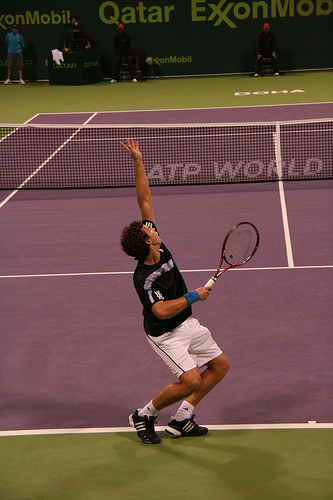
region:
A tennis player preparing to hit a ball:
[118, 135, 263, 447]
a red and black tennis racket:
[203, 222, 262, 288]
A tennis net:
[0, 115, 330, 190]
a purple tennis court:
[0, 101, 332, 435]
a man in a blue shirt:
[4, 25, 26, 83]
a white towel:
[50, 48, 63, 64]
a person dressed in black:
[253, 20, 281, 76]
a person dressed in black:
[110, 23, 142, 84]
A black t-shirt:
[132, 217, 193, 336]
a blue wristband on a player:
[182, 287, 201, 305]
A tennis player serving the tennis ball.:
[111, 137, 251, 446]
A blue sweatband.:
[182, 287, 199, 305]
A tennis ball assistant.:
[2, 23, 28, 88]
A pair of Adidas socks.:
[137, 399, 200, 422]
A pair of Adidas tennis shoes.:
[128, 407, 210, 446]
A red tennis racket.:
[199, 218, 264, 296]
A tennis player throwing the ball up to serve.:
[96, 134, 261, 446]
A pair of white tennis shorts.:
[137, 314, 238, 380]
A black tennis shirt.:
[119, 211, 203, 335]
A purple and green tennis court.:
[1, 87, 331, 445]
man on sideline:
[4, 21, 26, 88]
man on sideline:
[111, 19, 135, 86]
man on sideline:
[252, 20, 281, 78]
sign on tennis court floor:
[232, 86, 308, 95]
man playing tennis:
[62, 124, 263, 439]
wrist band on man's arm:
[181, 286, 200, 300]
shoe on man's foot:
[130, 409, 159, 443]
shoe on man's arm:
[161, 413, 205, 435]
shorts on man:
[144, 316, 221, 367]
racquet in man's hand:
[201, 206, 268, 301]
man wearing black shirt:
[89, 137, 271, 445]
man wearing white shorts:
[124, 212, 246, 446]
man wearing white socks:
[123, 211, 228, 463]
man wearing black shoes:
[118, 202, 240, 454]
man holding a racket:
[85, 103, 327, 459]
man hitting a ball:
[122, 116, 242, 437]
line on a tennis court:
[231, 405, 316, 430]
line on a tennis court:
[11, 255, 100, 278]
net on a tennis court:
[171, 110, 313, 184]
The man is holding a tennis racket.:
[100, 131, 266, 453]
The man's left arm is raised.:
[102, 119, 264, 454]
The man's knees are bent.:
[104, 127, 272, 450]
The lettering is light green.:
[97, 0, 120, 27]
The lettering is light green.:
[118, 3, 138, 27]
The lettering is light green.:
[135, 0, 148, 26]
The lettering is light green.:
[145, 3, 164, 27]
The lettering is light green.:
[161, 1, 180, 26]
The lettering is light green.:
[22, 8, 41, 26]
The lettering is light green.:
[47, 8, 62, 26]